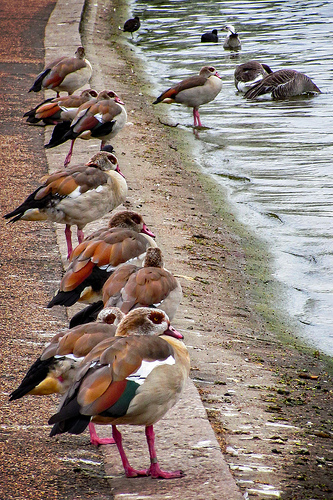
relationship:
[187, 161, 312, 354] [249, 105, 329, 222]
mold by water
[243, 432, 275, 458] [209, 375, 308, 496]
snow on ground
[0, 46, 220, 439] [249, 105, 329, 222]
bird in water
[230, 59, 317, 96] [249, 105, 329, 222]
duck in water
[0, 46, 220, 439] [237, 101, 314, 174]
bird near lake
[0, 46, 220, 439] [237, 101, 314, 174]
bird ear lake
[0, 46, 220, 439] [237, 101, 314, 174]
bird in lake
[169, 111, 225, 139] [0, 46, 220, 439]
leg of bird